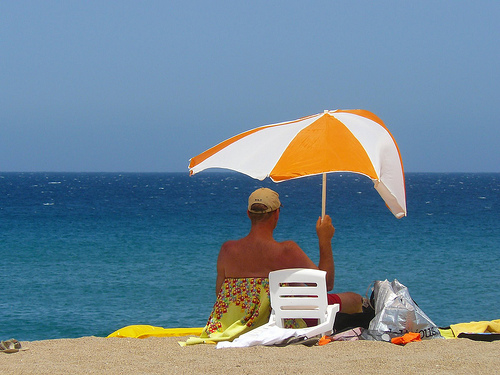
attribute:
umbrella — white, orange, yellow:
[188, 110, 406, 218]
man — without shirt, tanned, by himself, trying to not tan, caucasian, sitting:
[216, 188, 364, 313]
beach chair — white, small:
[268, 268, 340, 345]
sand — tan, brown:
[0, 336, 499, 374]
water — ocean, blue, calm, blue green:
[0, 173, 499, 341]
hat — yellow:
[248, 186, 282, 213]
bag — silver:
[361, 283, 445, 340]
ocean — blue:
[1, 172, 499, 342]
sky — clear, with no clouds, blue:
[0, 2, 497, 175]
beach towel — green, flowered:
[178, 278, 308, 348]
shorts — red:
[330, 292, 342, 313]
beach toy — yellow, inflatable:
[107, 324, 206, 339]